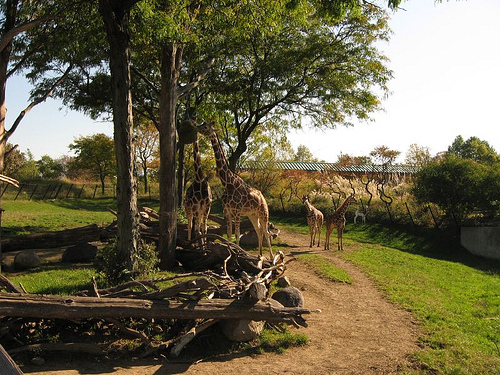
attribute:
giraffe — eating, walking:
[193, 120, 275, 258]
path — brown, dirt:
[176, 216, 413, 373]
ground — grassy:
[1, 216, 498, 375]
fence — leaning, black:
[254, 195, 460, 228]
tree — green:
[24, 4, 397, 230]